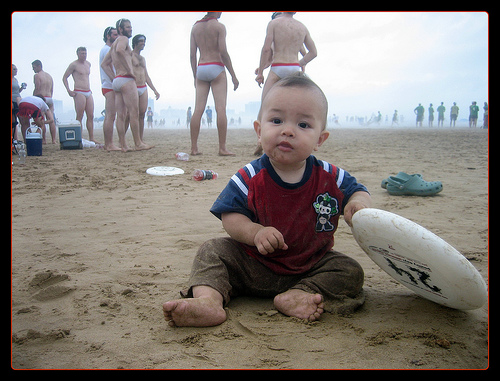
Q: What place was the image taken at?
A: It was taken at the beach.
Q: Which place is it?
A: It is a beach.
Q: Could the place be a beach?
A: Yes, it is a beach.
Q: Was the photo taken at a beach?
A: Yes, it was taken in a beach.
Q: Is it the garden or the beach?
A: It is the beach.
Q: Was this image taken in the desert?
A: No, the picture was taken in the beach.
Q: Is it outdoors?
A: Yes, it is outdoors.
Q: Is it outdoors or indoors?
A: It is outdoors.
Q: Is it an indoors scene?
A: No, it is outdoors.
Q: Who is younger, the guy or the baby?
A: The baby is younger than the guy.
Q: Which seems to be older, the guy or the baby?
A: The guy is older than the baby.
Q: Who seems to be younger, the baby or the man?
A: The baby is younger than the man.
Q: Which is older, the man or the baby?
A: The man is older than the baby.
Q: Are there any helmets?
A: No, there are no helmets.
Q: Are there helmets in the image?
A: No, there are no helmets.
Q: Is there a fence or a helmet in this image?
A: No, there are no helmets or fences.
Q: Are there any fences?
A: No, there are no fences.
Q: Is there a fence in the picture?
A: No, there are no fences.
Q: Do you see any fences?
A: No, there are no fences.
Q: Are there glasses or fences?
A: No, there are no fences or glasses.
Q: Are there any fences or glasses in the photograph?
A: No, there are no fences or glasses.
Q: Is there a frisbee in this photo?
A: Yes, there is a frisbee.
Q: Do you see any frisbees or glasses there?
A: Yes, there is a frisbee.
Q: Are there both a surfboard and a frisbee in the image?
A: No, there is a frisbee but no surfboards.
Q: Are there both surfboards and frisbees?
A: No, there is a frisbee but no surfboards.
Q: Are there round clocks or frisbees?
A: Yes, there is a round frisbee.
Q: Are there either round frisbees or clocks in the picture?
A: Yes, there is a round frisbee.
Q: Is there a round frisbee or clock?
A: Yes, there is a round frisbee.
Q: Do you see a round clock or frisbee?
A: Yes, there is a round frisbee.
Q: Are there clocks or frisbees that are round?
A: Yes, the frisbee is round.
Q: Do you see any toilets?
A: No, there are no toilets.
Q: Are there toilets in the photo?
A: No, there are no toilets.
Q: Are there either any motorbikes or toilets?
A: No, there are no toilets or motorbikes.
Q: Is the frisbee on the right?
A: Yes, the frisbee is on the right of the image.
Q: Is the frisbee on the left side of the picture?
A: No, the frisbee is on the right of the image.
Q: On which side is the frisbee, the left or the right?
A: The frisbee is on the right of the image.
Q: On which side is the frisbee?
A: The frisbee is on the right of the image.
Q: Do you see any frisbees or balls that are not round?
A: No, there is a frisbee but it is round.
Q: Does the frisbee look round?
A: Yes, the frisbee is round.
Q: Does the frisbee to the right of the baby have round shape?
A: Yes, the frisbee is round.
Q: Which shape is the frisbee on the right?
A: The frisbee is round.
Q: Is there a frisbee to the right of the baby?
A: Yes, there is a frisbee to the right of the baby.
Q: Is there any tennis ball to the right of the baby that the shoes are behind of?
A: No, there is a frisbee to the right of the baby.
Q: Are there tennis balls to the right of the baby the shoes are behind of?
A: No, there is a frisbee to the right of the baby.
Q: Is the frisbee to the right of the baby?
A: Yes, the frisbee is to the right of the baby.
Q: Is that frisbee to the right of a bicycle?
A: No, the frisbee is to the right of the baby.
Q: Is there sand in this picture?
A: Yes, there is sand.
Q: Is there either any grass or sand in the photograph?
A: Yes, there is sand.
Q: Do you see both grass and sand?
A: No, there is sand but no grass.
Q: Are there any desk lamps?
A: No, there are no desk lamps.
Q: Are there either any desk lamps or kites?
A: No, there are no desk lamps or kites.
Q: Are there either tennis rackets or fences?
A: No, there are no fences or tennis rackets.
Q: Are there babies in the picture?
A: Yes, there is a baby.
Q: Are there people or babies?
A: Yes, there is a baby.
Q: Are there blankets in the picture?
A: No, there are no blankets.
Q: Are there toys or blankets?
A: No, there are no blankets or toys.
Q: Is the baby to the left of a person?
A: No, the baby is to the right of a person.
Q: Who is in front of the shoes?
A: The baby is in front of the shoes.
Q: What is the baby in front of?
A: The baby is in front of the shoes.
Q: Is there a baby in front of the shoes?
A: Yes, there is a baby in front of the shoes.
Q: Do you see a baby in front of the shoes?
A: Yes, there is a baby in front of the shoes.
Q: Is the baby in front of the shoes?
A: Yes, the baby is in front of the shoes.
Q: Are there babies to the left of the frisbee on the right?
A: Yes, there is a baby to the left of the frisbee.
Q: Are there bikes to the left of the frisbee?
A: No, there is a baby to the left of the frisbee.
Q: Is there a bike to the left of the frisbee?
A: No, there is a baby to the left of the frisbee.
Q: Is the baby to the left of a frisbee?
A: Yes, the baby is to the left of a frisbee.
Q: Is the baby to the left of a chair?
A: No, the baby is to the left of a frisbee.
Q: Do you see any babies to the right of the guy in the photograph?
A: Yes, there is a baby to the right of the guy.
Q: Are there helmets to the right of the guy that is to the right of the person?
A: No, there is a baby to the right of the guy.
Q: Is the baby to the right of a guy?
A: Yes, the baby is to the right of a guy.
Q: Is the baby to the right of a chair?
A: No, the baby is to the right of a guy.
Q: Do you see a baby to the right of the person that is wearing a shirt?
A: Yes, there is a baby to the right of the person.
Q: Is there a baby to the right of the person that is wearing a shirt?
A: Yes, there is a baby to the right of the person.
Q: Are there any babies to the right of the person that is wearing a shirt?
A: Yes, there is a baby to the right of the person.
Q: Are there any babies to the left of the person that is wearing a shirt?
A: No, the baby is to the right of the person.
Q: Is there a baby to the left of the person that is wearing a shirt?
A: No, the baby is to the right of the person.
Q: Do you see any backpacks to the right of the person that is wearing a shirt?
A: No, there is a baby to the right of the person.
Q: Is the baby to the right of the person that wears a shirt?
A: Yes, the baby is to the right of the person.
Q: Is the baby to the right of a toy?
A: No, the baby is to the right of the person.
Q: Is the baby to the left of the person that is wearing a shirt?
A: No, the baby is to the right of the person.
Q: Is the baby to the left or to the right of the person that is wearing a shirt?
A: The baby is to the right of the person.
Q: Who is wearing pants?
A: The baby is wearing pants.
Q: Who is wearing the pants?
A: The baby is wearing pants.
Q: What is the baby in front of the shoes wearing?
A: The baby is wearing pants.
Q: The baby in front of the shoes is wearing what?
A: The baby is wearing pants.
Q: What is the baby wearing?
A: The baby is wearing pants.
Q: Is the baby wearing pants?
A: Yes, the baby is wearing pants.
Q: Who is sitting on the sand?
A: The baby is sitting on the sand.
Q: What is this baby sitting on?
A: The baby is sitting on the sand.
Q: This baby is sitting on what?
A: The baby is sitting on the sand.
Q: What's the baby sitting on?
A: The baby is sitting on the sand.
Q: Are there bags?
A: No, there are no bags.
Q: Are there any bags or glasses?
A: No, there are no bags or glasses.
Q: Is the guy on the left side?
A: Yes, the guy is on the left of the image.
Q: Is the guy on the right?
A: No, the guy is on the left of the image.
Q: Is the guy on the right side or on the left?
A: The guy is on the left of the image.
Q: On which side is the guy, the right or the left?
A: The guy is on the left of the image.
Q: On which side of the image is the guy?
A: The guy is on the left of the image.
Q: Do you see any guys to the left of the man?
A: Yes, there is a guy to the left of the man.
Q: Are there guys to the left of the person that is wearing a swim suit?
A: Yes, there is a guy to the left of the man.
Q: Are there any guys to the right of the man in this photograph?
A: No, the guy is to the left of the man.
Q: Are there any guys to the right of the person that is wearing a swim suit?
A: No, the guy is to the left of the man.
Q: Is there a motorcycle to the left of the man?
A: No, there is a guy to the left of the man.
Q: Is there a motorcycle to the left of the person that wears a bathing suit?
A: No, there is a guy to the left of the man.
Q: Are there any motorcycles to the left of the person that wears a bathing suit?
A: No, there is a guy to the left of the man.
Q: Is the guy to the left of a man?
A: Yes, the guy is to the left of a man.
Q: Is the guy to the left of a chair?
A: No, the guy is to the left of a man.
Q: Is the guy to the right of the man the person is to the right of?
A: No, the guy is to the left of the man.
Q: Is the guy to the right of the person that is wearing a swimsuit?
A: No, the guy is to the left of the man.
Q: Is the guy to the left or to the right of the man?
A: The guy is to the left of the man.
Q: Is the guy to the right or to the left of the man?
A: The guy is to the left of the man.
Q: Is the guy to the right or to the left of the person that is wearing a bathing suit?
A: The guy is to the left of the man.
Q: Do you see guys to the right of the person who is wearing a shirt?
A: Yes, there is a guy to the right of the person.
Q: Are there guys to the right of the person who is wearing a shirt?
A: Yes, there is a guy to the right of the person.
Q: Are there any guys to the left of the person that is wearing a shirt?
A: No, the guy is to the right of the person.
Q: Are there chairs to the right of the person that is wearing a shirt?
A: No, there is a guy to the right of the person.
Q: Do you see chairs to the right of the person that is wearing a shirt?
A: No, there is a guy to the right of the person.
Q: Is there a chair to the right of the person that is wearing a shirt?
A: No, there is a guy to the right of the person.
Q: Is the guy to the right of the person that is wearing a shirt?
A: Yes, the guy is to the right of the person.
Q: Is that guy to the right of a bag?
A: No, the guy is to the right of the person.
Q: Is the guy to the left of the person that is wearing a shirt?
A: No, the guy is to the right of the person.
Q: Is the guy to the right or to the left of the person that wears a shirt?
A: The guy is to the right of the person.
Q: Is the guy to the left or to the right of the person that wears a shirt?
A: The guy is to the right of the person.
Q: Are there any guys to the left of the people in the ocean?
A: Yes, there is a guy to the left of the people.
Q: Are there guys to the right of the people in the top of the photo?
A: No, the guy is to the left of the people.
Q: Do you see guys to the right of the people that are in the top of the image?
A: No, the guy is to the left of the people.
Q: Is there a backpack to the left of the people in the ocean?
A: No, there is a guy to the left of the people.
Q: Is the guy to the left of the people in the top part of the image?
A: Yes, the guy is to the left of the people.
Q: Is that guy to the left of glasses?
A: No, the guy is to the left of the people.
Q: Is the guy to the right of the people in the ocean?
A: No, the guy is to the left of the people.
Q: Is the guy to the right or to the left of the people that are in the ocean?
A: The guy is to the left of the people.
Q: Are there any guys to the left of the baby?
A: Yes, there is a guy to the left of the baby.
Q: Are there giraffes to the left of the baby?
A: No, there is a guy to the left of the baby.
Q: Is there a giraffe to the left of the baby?
A: No, there is a guy to the left of the baby.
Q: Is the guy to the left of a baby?
A: Yes, the guy is to the left of a baby.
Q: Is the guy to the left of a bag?
A: No, the guy is to the left of a baby.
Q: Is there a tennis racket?
A: No, there are no rackets.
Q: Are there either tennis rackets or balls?
A: No, there are no tennis rackets or balls.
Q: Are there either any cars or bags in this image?
A: No, there are no bags or cars.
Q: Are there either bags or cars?
A: No, there are no bags or cars.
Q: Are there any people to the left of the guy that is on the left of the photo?
A: Yes, there is a person to the left of the guy.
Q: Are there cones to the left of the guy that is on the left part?
A: No, there is a person to the left of the guy.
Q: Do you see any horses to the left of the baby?
A: No, there is a person to the left of the baby.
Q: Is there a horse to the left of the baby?
A: No, there is a person to the left of the baby.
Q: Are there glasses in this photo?
A: No, there are no glasses.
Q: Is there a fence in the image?
A: No, there are no fences.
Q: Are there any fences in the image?
A: No, there are no fences.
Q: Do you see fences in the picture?
A: No, there are no fences.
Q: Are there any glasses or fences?
A: No, there are no fences or glasses.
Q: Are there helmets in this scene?
A: No, there are no helmets.